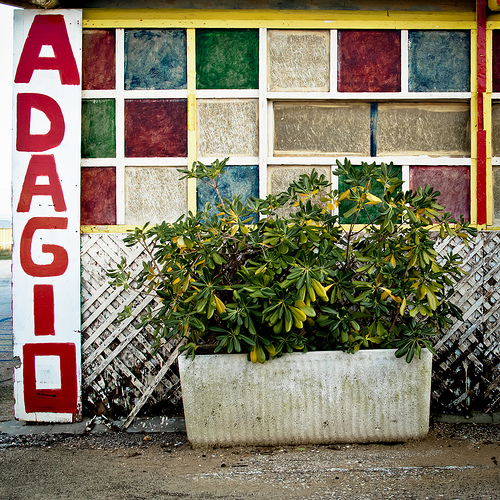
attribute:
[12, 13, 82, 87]
letter — red, top, vertical, a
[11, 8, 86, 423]
sign — white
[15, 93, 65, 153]
letter — red, d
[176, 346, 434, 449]
pot — white, planter box, dirty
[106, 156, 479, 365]
plant — green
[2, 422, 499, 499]
ground — dirt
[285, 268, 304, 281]
leaf — green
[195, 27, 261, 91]
tile — colored, different, green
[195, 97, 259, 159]
tile — colorful, white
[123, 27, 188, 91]
tile — blue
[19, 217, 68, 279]
letter — g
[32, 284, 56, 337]
letter — i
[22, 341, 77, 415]
letter — o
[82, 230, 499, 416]
trellis — dirty, white, moldy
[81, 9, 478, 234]
trim — yellow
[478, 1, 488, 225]
trim — red